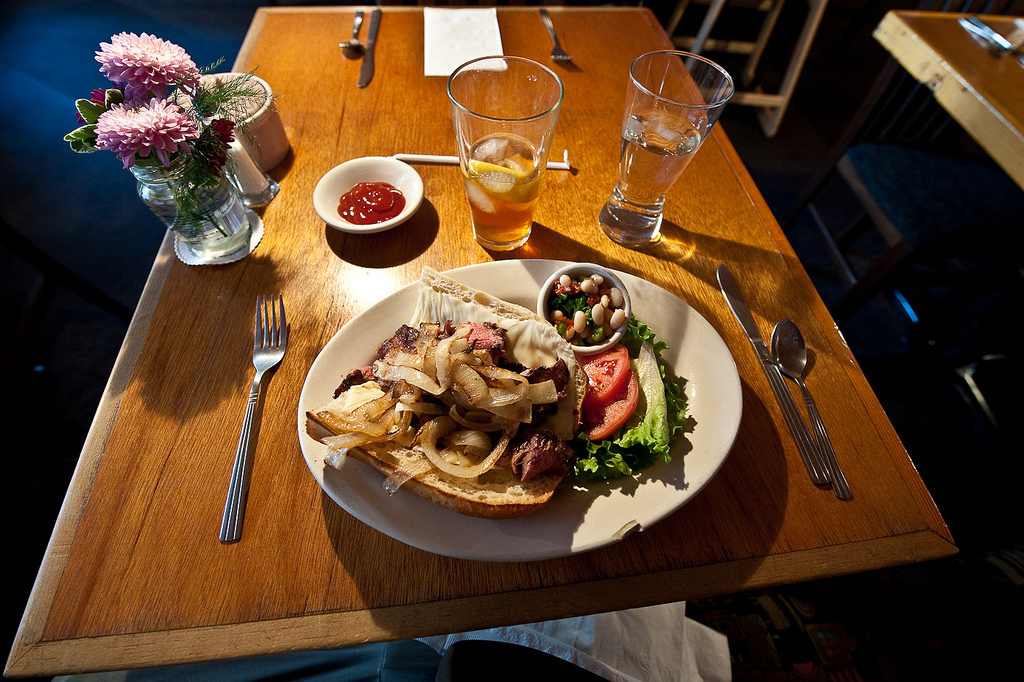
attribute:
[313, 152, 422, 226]
bowl — small, white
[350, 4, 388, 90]
knife — gray, butter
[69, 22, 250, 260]
flowers — pink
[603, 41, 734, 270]
glass — tall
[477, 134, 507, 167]
ice — piece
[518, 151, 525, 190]
ice — piece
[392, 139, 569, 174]
straw — long, white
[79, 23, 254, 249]
flowers — purple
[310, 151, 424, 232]
bowl — small, white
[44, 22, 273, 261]
vase — clear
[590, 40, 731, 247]
glass — clear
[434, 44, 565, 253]
glass — clear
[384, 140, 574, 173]
drinkingstraw — covered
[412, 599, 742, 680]
napkin — white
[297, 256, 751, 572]
plate — round, white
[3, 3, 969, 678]
table — large, wooden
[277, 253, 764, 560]
plate — large, white